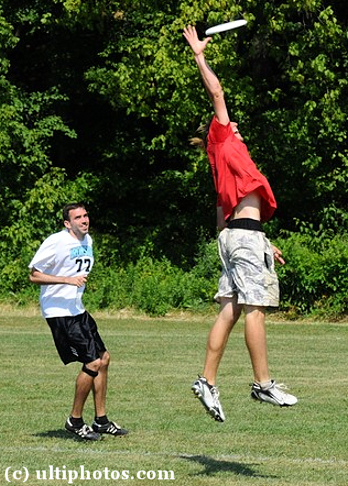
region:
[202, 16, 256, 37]
A white Frisbee in the air.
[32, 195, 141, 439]
A man wearing white shirt.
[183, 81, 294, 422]
A man jumping in the air.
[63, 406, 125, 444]
Black and white tennis shoes.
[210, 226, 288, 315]
Tan khaki shorts.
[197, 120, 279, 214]
A red t-shirt.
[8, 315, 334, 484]
A green grassy field.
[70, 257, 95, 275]
Black 77 on a shirt.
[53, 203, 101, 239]
A man with a smile on face.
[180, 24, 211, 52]
A hand catching a Frisbee.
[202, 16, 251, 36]
A white frisbee flying in the air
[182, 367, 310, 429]
A pair of feet off the ground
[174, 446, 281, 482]
The shadow of a person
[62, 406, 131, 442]
A pair of black sneakers with white stripes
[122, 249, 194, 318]
Green bushes in the background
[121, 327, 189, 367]
yellow green grass on the ground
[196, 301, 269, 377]
A pair of bare legs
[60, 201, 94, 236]
Teh face of a man smiling and looking up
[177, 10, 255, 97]
An arm and hand reaching for a frisbee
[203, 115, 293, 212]
A person wearing a red tee shirt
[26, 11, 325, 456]
two guys playing frisbee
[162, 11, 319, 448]
man jumping in the air to catch the frisbee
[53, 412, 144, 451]
black and white shoes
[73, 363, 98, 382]
black band around the leg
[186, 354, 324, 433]
both feet high off the ground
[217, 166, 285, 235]
shirt blowing up and exposing skin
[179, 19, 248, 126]
arm stretched out to catch frisbee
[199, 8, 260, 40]
white frisbee flying in the air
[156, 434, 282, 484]
shadow form the man jumping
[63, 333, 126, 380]
knees slightly bent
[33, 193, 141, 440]
Man watching other man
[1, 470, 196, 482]
Photo credit shown in white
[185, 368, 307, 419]
Cleats are white and spiky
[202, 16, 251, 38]
Frisbee is round and white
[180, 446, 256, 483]
Man's shadow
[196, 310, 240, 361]
Calf muscle is clenched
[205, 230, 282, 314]
Shorts are white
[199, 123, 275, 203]
Shirt is red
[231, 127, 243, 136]
Mouth is opened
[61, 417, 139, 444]
Shoes are black and white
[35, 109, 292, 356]
The two men play disc football.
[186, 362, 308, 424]
The man is wearing white cleats.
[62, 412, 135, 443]
The man is wearing black cleats.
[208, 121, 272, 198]
The man is wearing a red shirt.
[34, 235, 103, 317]
The man is wearing a white jersey.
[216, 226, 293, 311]
The shorts are white and grey.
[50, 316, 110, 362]
The shorts are black.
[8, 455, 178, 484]
The website is ultiphotos.com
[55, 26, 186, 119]
The trees are green.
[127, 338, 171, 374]
The grass is green.